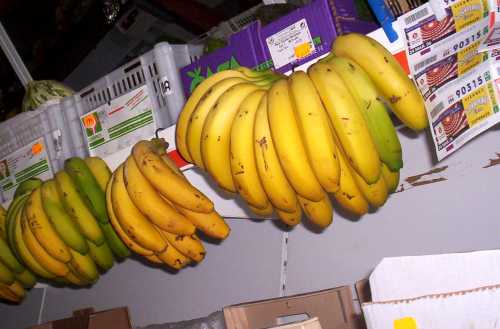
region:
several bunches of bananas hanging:
[4, 91, 421, 283]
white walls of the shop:
[176, 248, 256, 303]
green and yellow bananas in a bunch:
[31, 175, 124, 275]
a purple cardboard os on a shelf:
[180, 3, 339, 104]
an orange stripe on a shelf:
[161, 141, 191, 169]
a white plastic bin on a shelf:
[76, 47, 168, 161]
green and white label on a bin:
[83, 86, 148, 158]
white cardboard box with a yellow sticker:
[348, 251, 497, 326]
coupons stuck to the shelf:
[397, 1, 497, 158]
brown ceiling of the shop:
[8, 9, 79, 60]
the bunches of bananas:
[0, 34, 426, 304]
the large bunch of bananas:
[175, 32, 427, 227]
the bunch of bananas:
[105, 135, 229, 272]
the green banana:
[62, 155, 107, 223]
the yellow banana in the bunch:
[268, 79, 323, 202]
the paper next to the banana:
[397, 2, 498, 162]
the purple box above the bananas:
[177, 3, 383, 103]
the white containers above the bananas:
[1, 40, 206, 212]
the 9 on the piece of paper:
[455, 88, 461, 100]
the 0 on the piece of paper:
[459, 84, 466, 95]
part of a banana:
[238, 170, 261, 210]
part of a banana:
[251, 133, 268, 175]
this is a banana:
[264, 73, 321, 179]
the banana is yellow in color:
[263, 97, 287, 139]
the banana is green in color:
[78, 165, 88, 205]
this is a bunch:
[192, 62, 420, 187]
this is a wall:
[441, 170, 498, 219]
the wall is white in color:
[438, 178, 495, 223]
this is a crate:
[86, 67, 173, 118]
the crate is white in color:
[120, 60, 158, 90]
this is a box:
[388, 266, 498, 316]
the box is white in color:
[416, 266, 479, 303]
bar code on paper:
[404, 5, 431, 27]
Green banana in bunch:
[55, 152, 111, 224]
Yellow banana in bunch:
[265, 73, 322, 207]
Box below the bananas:
[217, 281, 362, 327]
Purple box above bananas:
[175, 0, 380, 116]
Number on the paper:
[454, 69, 486, 104]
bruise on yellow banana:
[251, 134, 276, 171]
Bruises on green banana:
[357, 89, 388, 120]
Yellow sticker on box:
[289, 38, 316, 62]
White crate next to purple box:
[67, 37, 202, 162]